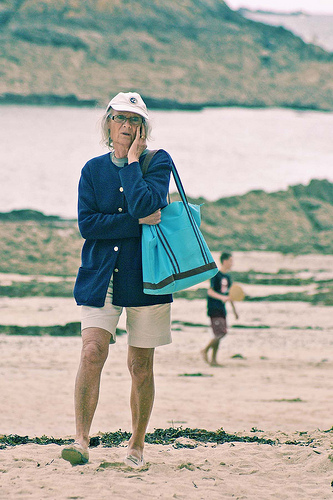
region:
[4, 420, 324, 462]
The beach has sea weed on the sand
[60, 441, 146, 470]
The woman is wearing shoes in the sand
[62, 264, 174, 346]
The woman is wearing a short pant.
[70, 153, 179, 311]
The blue sweater has pockets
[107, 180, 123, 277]
The buttons on the sweater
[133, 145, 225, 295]
The woman is carrying a blue tote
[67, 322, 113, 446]
A woman's right leg.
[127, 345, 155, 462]
A woman's left leg.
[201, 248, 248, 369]
A young boy on a beach.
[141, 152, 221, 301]
A light blue hand bag.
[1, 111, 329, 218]
A body of water between land.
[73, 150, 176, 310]
A woman in a blue sweater.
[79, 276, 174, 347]
A pair of white shorts.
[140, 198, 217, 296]
A bag with black lines on it.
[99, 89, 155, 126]
a white hat on a woman's head.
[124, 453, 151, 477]
a shoe on a woman's left foot.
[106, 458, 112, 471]
white sand on the ground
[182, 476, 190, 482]
white sand on the ground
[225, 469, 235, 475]
white sand on the ground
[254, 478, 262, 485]
white sand on the ground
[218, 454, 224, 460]
white sand on the ground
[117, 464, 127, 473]
white sand on the ground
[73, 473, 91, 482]
white sand on the ground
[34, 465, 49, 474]
white sand on the ground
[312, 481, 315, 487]
white sand on the ground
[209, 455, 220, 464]
white sand on the ground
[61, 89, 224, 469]
woman walking on the beach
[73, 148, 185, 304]
blue sweater the woman is wearing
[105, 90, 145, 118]
white hat the woman is wearing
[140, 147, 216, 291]
teal and black bag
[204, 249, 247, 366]
boy wearing black shirt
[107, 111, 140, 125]
eyeglasses woman is wearing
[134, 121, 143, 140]
cellphone woman is holding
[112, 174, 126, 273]
buttons on woman's sweater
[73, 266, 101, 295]
pocket on woman's blue sweater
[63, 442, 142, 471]
shoes woman is wearing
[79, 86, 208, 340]
An old woman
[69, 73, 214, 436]
An old woman with a handbag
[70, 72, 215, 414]
A woman with a cap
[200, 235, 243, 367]
A young man in the background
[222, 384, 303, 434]
Sandy soil on the ground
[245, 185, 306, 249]
Hills in the background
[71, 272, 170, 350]
A pair of shorts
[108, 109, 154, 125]
Glasses on the eyes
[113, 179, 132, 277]
Buttons on the sweater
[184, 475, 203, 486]
a footstep on sand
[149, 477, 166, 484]
a footstep on sand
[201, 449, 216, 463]
a footstep on sand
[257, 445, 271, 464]
a footstep on sand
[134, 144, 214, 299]
woman holding a blue bag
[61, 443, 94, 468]
The left shoe of the woman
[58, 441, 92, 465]
A left shoe on the woman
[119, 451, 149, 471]
The right shoe on the woman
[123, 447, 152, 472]
A right shoe on the woman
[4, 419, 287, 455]
The seaweed behind the woman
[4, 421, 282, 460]
A set of seaweed behind the woman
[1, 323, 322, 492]
The sandy area